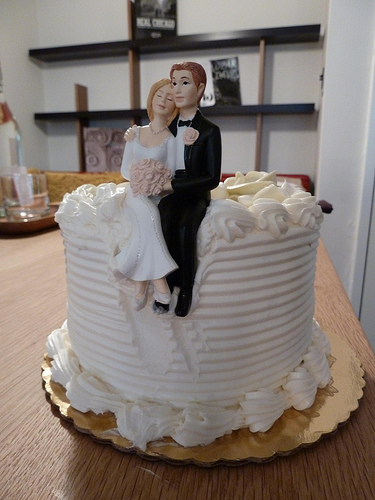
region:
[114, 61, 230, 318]
Wedding couple figures sit atop wedding cake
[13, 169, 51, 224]
glass on tray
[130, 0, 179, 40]
Real Chicago book on shelf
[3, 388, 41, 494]
Wood grain table top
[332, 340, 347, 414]
gold foil atop wedding cake tray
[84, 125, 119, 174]
floral, conch relief artwork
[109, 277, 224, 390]
wedding cake artifice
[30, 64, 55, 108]
left corner of room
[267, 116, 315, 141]
shadow cast by shelving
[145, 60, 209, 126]
Wedding cake figurines depict loving moment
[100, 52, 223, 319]
The man and woman cake topper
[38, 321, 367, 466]
The plate the cake is on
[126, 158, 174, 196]
The bouquet on the cake topper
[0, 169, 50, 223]
The glasses near the bottle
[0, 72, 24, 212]
The bottle near the glasses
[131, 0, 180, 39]
The black book on the top shelf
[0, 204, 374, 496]
the table the cake is on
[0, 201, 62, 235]
Tray holding the glasses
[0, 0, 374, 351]
The white walls in the background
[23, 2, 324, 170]
The black and brown book case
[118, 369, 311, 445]
Frosting on bottom of cake.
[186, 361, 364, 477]
Card board cake stand .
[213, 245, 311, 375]
A white patch of frosting.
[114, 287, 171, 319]
A white pair of shoes.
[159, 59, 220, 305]
A man in a tuxedo.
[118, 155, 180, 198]
A pink bouquet of flowers.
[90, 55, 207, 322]
Bride and groom on cake.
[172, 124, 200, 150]
Small flower on suit jacket.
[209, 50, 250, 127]
Book on a shelf.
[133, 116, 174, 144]
Necklace on a doll.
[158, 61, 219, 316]
Man is sitting on cake.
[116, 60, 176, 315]
Woman is sitting cake.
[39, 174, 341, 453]
Cake has white froating.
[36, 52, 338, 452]
Wedding cake is small.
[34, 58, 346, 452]
The wedding cake is simple in design.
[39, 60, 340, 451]
The wedding cake is beautiful.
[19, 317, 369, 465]
Cake is sitting on cardboard.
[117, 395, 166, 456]
There's a finger smudge in icing.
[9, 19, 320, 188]
There are black shelves on back wall.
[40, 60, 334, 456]
The cake hasn't been cut yet.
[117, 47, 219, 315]
female and male figures on a wedding cake tier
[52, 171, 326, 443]
wedding cake tier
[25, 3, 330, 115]
black bookshelves with two books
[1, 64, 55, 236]
champagne bottle and glasses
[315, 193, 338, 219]
purple frosting flower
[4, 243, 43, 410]
brown wooden table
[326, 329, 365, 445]
circular cardboard holding cake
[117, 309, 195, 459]
smeared white frosting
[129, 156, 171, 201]
replica of bouquet of pink flowers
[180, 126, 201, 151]
replica of pink boutinerre